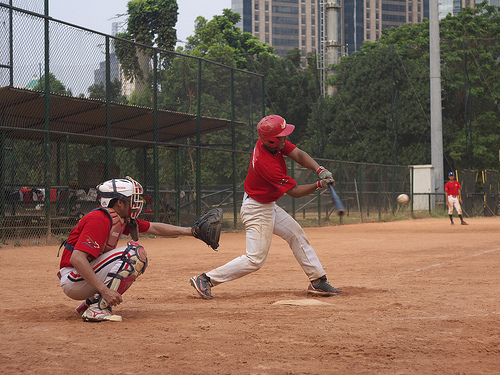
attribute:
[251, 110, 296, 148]
batting helmet — red 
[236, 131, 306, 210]
red shirt — red 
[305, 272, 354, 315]
black shoes — black 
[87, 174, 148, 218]
white helmet — white 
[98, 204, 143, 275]
chest guard — red 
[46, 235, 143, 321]
white pants — white 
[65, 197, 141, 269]
red shirt — red 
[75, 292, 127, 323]
white shoes — white 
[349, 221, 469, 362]
dirt — brown 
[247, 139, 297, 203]
shirt — red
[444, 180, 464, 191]
shirt — red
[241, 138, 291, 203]
shirt — red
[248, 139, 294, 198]
shirt — red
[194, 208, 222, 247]
catcher's mitt — black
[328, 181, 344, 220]
bat — black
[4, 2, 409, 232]
fence — green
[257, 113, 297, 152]
helmet — red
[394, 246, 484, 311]
lines — fading, white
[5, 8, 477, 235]
fence — green, wired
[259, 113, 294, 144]
helmet — red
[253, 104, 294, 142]
helmet — red